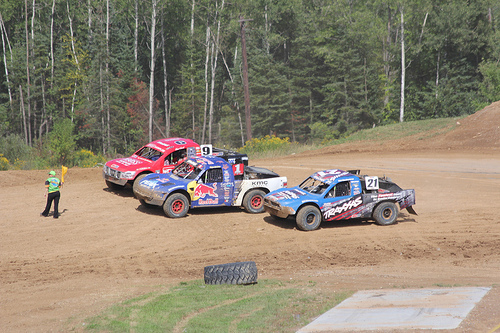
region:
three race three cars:
[91, 118, 438, 256]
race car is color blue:
[253, 160, 423, 233]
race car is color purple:
[130, 150, 290, 220]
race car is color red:
[97, 123, 202, 195]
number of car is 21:
[263, 159, 416, 231]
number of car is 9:
[136, 140, 286, 217]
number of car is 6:
[96, 123, 201, 195]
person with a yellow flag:
[36, 160, 73, 220]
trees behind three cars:
[0, 5, 499, 227]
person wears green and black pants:
[36, 156, 73, 222]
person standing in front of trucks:
[24, 130, 430, 330]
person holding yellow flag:
[27, 150, 107, 237]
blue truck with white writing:
[269, 147, 442, 252]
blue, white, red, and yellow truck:
[144, 140, 274, 215]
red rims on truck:
[112, 137, 287, 229]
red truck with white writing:
[97, 109, 199, 187]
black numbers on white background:
[355, 162, 392, 207]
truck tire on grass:
[162, 215, 322, 326]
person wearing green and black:
[19, 140, 93, 249]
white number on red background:
[220, 147, 257, 195]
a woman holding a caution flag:
[40, 160, 72, 220]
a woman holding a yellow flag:
[32, 151, 75, 222]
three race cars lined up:
[85, 101, 445, 241]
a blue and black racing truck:
[261, 163, 423, 230]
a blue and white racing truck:
[133, 140, 286, 222]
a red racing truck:
[100, 137, 202, 191]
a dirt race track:
[7, 200, 493, 310]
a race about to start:
[6, 40, 442, 251]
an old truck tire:
[196, 255, 266, 295]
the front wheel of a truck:
[295, 201, 323, 231]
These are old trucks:
[120, 87, 458, 277]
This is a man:
[20, 141, 131, 320]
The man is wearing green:
[31, 175, 104, 265]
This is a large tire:
[178, 197, 260, 308]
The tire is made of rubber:
[195, 223, 250, 299]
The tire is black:
[191, 242, 264, 317]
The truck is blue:
[261, 174, 360, 281]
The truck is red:
[125, 124, 237, 171]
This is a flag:
[35, 142, 180, 215]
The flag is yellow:
[36, 139, 102, 239]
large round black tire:
[188, 250, 288, 298]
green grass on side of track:
[163, 295, 275, 325]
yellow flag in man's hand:
[61, 154, 78, 191]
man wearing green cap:
[41, 158, 61, 180]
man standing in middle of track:
[35, 159, 88, 228]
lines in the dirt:
[47, 249, 153, 269]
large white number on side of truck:
[351, 168, 388, 198]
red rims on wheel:
[243, 193, 268, 213]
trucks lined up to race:
[108, 118, 410, 246]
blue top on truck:
[181, 148, 230, 180]